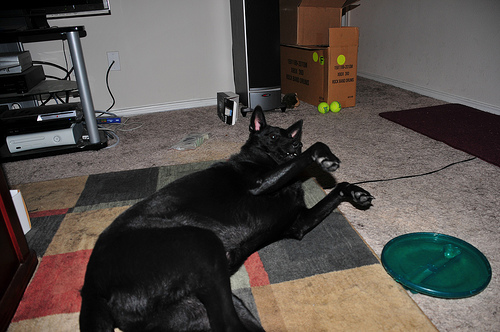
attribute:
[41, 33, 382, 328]
room — untidy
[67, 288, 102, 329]
tail — black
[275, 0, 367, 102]
boxes — cardboard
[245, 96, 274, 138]
ear — black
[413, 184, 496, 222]
carpeting — beige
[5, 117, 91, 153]
game — white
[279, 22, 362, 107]
box — cardboard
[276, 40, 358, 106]
box — cardboard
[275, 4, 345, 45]
box — cardboard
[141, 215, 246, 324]
back leg — black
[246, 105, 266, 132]
ear — black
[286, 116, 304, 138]
ear — black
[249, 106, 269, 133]
ear — pointy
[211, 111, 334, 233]
dog — black, color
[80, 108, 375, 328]
dog — color, black, big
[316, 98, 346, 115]
balls — green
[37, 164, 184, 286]
rug — colorful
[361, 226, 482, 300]
frisbee — green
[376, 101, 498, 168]
rug — black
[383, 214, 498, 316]
frisbee — green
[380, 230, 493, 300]
plate — green, plastic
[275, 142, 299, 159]
nose — black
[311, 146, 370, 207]
paws — black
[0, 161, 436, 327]
rug — colorful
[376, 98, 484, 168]
rug — maroon